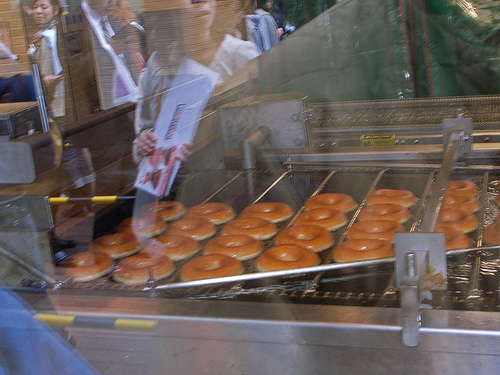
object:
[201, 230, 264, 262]
donut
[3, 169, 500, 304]
conveyer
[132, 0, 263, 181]
lady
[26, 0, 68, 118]
person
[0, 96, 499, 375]
machine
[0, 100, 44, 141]
box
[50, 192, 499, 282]
tray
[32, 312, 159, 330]
handle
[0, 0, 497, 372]
bar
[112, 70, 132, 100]
triangle